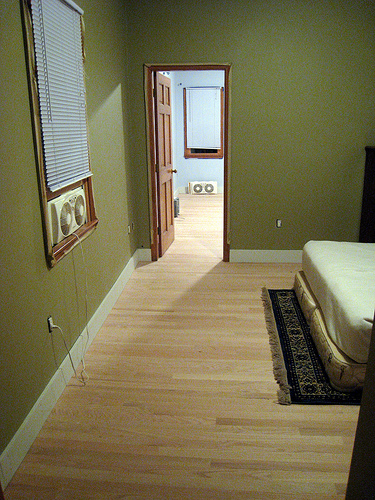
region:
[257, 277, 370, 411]
A rug underneath mattresses.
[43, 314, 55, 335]
Wall outlet on green wall.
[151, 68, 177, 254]
Brown wooden door.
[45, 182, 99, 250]
An ac unit in the window.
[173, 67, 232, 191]
Blue paint on the wall.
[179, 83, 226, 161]
Brown wood frame around the window.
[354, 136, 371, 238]
The end of a dark dresser.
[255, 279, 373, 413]
this is a rug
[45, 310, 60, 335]
this is an outlet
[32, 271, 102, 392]
this is a cable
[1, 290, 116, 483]
this is a baseboard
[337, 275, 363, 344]
this is a matress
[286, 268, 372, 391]
this is a boxspring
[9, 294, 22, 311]
this is the green wall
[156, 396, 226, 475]
this is the wooden floor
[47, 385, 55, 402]
this is the color white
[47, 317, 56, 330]
a white power outlet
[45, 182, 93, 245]
a wall mounted air conditioner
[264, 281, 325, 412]
a frilly carpet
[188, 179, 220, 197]
a white fan on the floor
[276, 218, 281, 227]
an empty wall outlet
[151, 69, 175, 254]
an open wooden door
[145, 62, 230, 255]
a wooden door frame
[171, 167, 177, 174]
a brass door knob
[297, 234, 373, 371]
the edge of a white mattress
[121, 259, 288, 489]
a hardwood floor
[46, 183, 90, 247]
Fan in the window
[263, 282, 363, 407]
Rug under the bed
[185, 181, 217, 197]
Fan on the floor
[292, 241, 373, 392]
Mattress and boxspring on the floor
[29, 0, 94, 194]
Blinds on the window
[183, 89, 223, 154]
Blinds on the window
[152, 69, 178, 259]
Open door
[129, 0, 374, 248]
Wall painted green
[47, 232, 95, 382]
Cord of fan plugged into the wall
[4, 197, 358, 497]
Wooden flooring in both rooms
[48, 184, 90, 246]
electric fans mounted on window.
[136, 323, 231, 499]
part of hard wood floors.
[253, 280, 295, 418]
part of a dark blue rug.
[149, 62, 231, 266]
bedroom entrance door.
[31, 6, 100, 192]
white window shades.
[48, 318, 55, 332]
small electrical plug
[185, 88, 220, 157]
wooden and rectangular window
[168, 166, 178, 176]
metal door knob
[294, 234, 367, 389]
part of mattresses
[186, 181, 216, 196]
double electrical fans on the floor.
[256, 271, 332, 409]
A rug under the bed.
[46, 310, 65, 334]
An electrical outlet on wall.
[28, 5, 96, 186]
The white blinds on the window.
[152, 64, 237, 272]
The door entrance into the room.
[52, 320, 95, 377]
Cord plugged into the wall.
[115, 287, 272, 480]
The flooring is wooden.